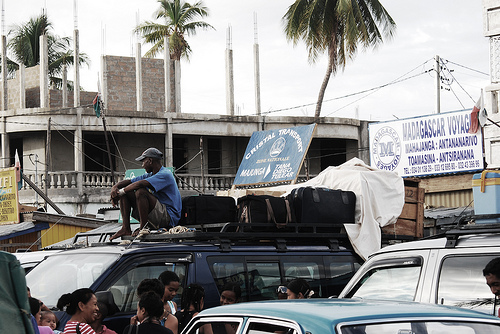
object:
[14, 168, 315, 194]
hand rail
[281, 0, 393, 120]
palm tree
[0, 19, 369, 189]
building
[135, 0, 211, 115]
palm tree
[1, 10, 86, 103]
palm tree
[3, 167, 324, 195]
balcony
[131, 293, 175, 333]
people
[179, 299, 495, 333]
car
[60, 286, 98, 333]
people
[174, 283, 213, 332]
people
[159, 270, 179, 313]
people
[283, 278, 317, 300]
people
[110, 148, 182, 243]
man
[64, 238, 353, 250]
roof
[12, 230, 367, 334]
car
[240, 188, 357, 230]
luggage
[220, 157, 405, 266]
sheet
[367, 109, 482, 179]
board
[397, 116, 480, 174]
letters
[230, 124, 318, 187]
board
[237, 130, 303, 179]
letters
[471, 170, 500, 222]
trunk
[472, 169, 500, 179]
edges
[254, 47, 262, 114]
pole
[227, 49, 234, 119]
pole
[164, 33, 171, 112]
pole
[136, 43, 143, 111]
pole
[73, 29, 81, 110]
pole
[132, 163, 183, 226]
shirt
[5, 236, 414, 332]
street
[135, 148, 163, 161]
cap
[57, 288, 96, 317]
hair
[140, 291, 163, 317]
hair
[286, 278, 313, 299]
hair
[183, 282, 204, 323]
hair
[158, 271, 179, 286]
hair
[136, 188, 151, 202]
knees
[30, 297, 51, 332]
woman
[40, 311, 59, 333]
child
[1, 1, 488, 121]
sky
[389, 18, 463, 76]
part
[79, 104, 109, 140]
part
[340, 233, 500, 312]
car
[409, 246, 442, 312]
part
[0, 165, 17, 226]
sign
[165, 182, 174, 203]
part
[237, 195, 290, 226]
bag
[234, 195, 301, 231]
middle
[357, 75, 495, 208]
right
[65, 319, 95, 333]
shirt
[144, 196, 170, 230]
short